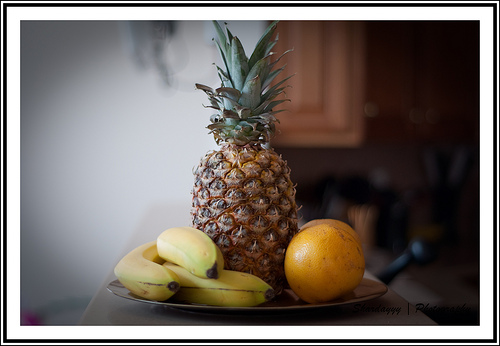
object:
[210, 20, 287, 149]
leaves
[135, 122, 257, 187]
wall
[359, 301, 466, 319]
tag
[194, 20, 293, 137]
top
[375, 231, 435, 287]
appliance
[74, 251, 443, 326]
table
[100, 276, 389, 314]
plate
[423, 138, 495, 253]
utensils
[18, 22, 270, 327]
wall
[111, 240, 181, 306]
banana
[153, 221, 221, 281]
banana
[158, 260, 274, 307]
banana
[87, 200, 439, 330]
counter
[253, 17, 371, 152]
cabinet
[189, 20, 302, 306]
fruits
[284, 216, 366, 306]
group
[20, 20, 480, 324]
background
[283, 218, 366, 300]
orange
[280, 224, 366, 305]
orange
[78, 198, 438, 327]
countertop